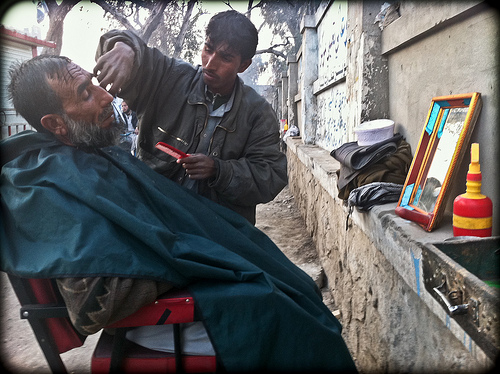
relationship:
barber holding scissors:
[92, 10, 288, 227] [88, 73, 128, 123]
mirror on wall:
[396, 89, 483, 233] [277, 1, 499, 372]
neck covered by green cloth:
[51, 117, 120, 160] [53, 137, 282, 292]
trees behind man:
[19, 2, 308, 131] [99, 10, 344, 227]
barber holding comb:
[92, 10, 288, 227] [155, 140, 186, 159]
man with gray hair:
[0, 54, 217, 358] [4, 50, 129, 149]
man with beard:
[0, 54, 217, 358] [58, 112, 130, 150]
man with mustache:
[0, 54, 217, 358] [88, 105, 118, 122]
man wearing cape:
[0, 54, 217, 358] [7, 132, 363, 372]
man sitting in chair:
[0, 54, 217, 358] [4, 180, 242, 369]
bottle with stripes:
[452, 142, 492, 235] [446, 185, 498, 235]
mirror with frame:
[393, 93, 483, 234] [389, 88, 483, 231]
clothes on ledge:
[328, 119, 412, 213] [287, 129, 483, 356]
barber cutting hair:
[92, 10, 288, 227] [108, 115, 128, 137]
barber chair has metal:
[2, 279, 218, 374] [32, 327, 57, 368]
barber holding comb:
[92, 10, 288, 227] [150, 132, 198, 164]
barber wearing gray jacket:
[92, 10, 288, 227] [133, 69, 295, 185]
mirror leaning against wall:
[393, 93, 483, 234] [405, 19, 492, 101]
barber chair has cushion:
[2, 133, 230, 370] [32, 277, 72, 347]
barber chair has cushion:
[2, 133, 230, 370] [88, 330, 208, 367]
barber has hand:
[93, 6, 288, 228] [178, 150, 213, 180]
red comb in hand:
[153, 137, 190, 162] [178, 150, 213, 180]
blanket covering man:
[5, 132, 313, 334] [13, 49, 300, 370]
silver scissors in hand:
[110, 102, 126, 127] [93, 43, 133, 93]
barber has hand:
[92, 10, 288, 227] [93, 43, 133, 93]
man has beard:
[0, 54, 217, 358] [82, 124, 124, 144]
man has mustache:
[0, 54, 217, 358] [102, 102, 114, 108]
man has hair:
[14, 58, 173, 368] [66, 114, 132, 151]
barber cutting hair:
[92, 10, 288, 227] [66, 114, 132, 151]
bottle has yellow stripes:
[454, 140, 484, 241] [433, 169, 496, 214]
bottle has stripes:
[454, 140, 484, 241] [454, 201, 477, 211]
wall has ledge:
[272, 125, 498, 371] [294, 144, 343, 188]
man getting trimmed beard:
[0, 54, 217, 358] [61, 119, 121, 148]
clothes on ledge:
[332, 112, 405, 210] [287, 129, 483, 356]